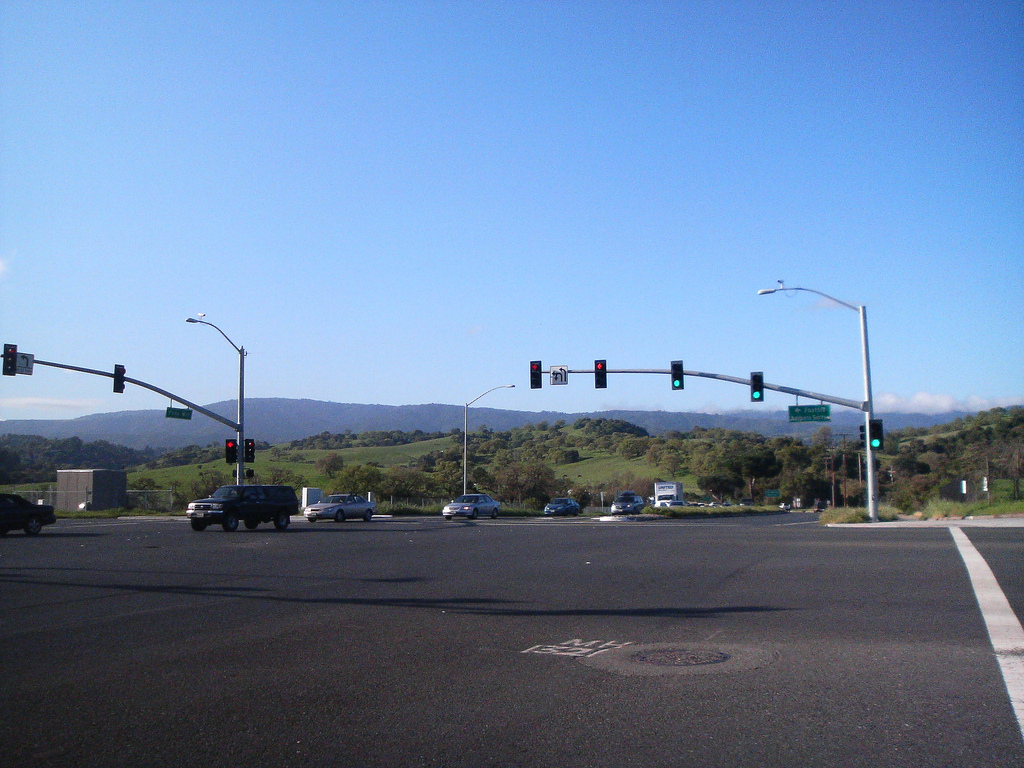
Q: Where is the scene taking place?
A: At an intersection.